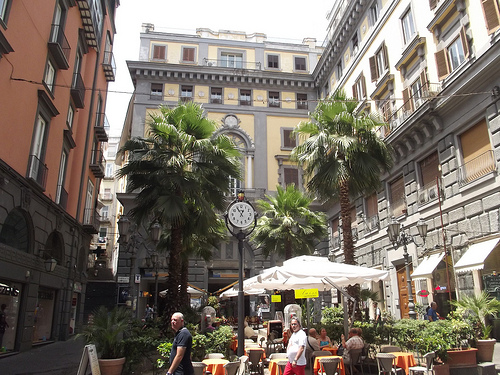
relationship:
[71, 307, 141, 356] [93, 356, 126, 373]
plant in pot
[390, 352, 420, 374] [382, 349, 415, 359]
cloth on table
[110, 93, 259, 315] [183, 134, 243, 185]
tree with leaves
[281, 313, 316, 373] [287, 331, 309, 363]
woman in shirt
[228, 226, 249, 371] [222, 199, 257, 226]
pole on clock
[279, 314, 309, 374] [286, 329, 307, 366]
man wearing shirt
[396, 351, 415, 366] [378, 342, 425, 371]
cloth on table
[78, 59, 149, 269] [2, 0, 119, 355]
balconies on building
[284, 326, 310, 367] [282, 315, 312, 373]
shirt on woman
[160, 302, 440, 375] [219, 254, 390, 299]
pedestrian under umbrella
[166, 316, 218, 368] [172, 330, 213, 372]
man wearing shirt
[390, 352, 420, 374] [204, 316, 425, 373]
cloth on tables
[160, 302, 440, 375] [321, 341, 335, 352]
pedestrian sitting around table